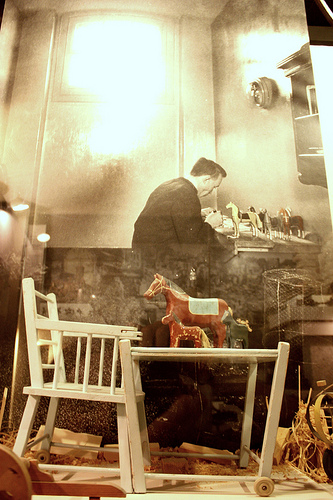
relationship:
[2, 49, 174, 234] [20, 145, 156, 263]
shelve on wall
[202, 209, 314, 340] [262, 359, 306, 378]
table has wheel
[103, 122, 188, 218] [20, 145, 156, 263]
shelf on wall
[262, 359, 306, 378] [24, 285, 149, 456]
wheel on chair